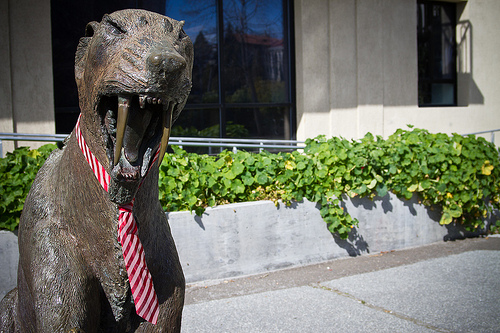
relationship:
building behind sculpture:
[1, 1, 499, 302] [15, 4, 200, 331]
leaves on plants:
[458, 164, 485, 196] [4, 140, 496, 250]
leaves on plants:
[349, 128, 388, 171] [4, 140, 496, 250]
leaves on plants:
[295, 161, 307, 171] [0, 128, 498, 242]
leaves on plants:
[227, 155, 272, 193] [0, 128, 498, 242]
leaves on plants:
[193, 206, 207, 216] [0, 128, 498, 242]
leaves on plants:
[180, 161, 220, 207] [0, 128, 498, 242]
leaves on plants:
[4, 147, 27, 177] [0, 128, 498, 242]